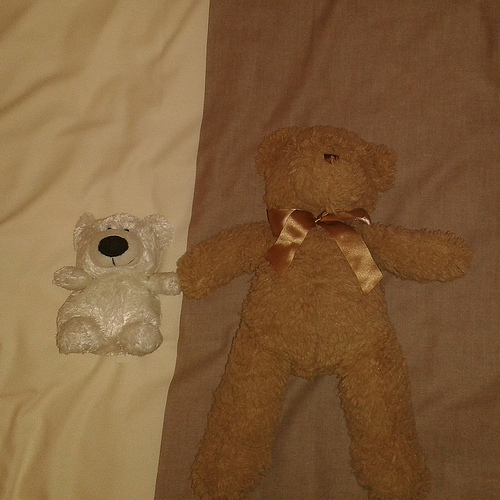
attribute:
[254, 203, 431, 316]
bow — brown 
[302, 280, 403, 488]
leg — brown 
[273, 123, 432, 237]
nose — brown 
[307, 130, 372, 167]
nose — black 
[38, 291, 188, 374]
legs — short 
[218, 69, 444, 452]
bear — small , white 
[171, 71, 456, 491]
bear — brown , large 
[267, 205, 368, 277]
bow — gold 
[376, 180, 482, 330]
arm — brown 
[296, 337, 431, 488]
leg — brown 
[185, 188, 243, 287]
arm — brown 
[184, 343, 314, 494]
leg — brown 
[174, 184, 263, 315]
arm — white 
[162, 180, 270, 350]
arm — white 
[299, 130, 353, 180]
nose — black 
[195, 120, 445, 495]
bear — brown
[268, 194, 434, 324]
ribbon — satin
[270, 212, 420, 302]
ribbon — brown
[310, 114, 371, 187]
nose — black 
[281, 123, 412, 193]
eyes — black 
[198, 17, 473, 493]
fabric — brown 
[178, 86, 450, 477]
bear — white 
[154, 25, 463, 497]
blanket — brown 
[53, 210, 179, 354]
bear toy — white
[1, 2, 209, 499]
blanket — white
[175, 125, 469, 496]
bear toy — brown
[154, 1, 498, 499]
blanket — brown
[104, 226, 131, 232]
eyes — black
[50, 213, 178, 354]
toy bear — white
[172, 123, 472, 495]
bear — brown,  brown teddy, head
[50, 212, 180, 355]
bear — black, white, nose 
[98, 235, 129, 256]
nose — black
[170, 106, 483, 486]
bear — big brown teddy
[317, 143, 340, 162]
bear — brown teddy , nose 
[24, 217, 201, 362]
bear — head, white teddy 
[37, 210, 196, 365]
animal — toy stuffed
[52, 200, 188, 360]
animal — toy stuffed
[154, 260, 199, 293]
animal — stuffed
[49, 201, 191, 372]
animal — stuffed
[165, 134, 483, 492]
animal — stuffed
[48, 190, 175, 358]
bear — white, stuffed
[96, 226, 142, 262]
nose — black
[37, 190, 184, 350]
nose — black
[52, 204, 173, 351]
bear — white 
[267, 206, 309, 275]
ribbon —  gold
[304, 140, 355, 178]
nose —  brown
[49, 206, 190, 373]
bear — light brown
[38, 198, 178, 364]
bear — stuffed animals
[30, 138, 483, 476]
bear —  lying down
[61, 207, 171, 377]
bear — small, white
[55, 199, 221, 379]
bear — white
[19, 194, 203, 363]
teddy bear — small , white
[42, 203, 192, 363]
animal — stuffed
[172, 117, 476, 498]
stuffed bear — brown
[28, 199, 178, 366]
stuffed bear — white 